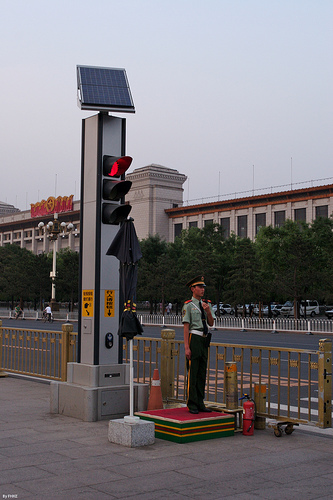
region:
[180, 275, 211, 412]
man in official uniform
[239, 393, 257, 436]
red fire extinguisher next to railing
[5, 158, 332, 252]
long building across the street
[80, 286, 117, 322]
black and yellow sign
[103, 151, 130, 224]
three lights on the traffic signal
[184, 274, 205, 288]
hat man is wearing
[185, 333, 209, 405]
green pants with yellow stripe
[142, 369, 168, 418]
orange safety cone with white stripe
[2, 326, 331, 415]
yellow railing along the street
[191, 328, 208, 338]
white belt of man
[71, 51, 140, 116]
black solar panel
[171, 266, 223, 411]
officer in uniform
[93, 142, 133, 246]
signal light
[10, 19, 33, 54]
white clouds in blue sky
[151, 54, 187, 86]
white clouds in blue sky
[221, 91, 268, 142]
white clouds in blue sky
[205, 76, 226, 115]
white clouds in blue sky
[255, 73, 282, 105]
white clouds in blue sky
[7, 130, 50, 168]
white clouds in blue sky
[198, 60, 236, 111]
white clouds in blue sky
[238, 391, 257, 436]
Red fire extinguisher on sidewalk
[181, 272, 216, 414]
Security officer standing at attention on sidewalk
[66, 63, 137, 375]
Solar powered street traffic light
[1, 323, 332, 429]
Sliding metal safety gate.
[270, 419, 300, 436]
Roller caster wheels on sliding gate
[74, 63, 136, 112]
Solar electric generation panel.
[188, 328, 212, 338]
White utility belt on guard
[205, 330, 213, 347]
Walkie talkie radio hooked on belt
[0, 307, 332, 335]
Long white metal fence running along city street.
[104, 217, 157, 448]
Shade umbrella mounted in heavy cement block on sidewalk.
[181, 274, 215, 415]
an example of how people should stand to have good posture all their life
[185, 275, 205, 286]
hat with gold brim indicating officer of some sort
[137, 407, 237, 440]
podium for man to stand on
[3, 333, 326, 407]
fence to set boundaries for cars and people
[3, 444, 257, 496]
sidewalk for people to walk on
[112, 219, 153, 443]
umbrella for guard in case of shower s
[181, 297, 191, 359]
hands and arms to the side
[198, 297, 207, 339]
tie around neck indicating professionalism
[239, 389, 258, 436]
fire hydrant in case o fire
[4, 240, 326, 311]
hedge of trees for landscaping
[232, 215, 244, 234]
window on the building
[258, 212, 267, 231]
window on the building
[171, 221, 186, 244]
window on the building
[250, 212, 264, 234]
window on the building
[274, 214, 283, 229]
window on the building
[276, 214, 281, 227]
window on the building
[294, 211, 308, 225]
window on the building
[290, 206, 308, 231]
window on the building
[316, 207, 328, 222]
window on the building